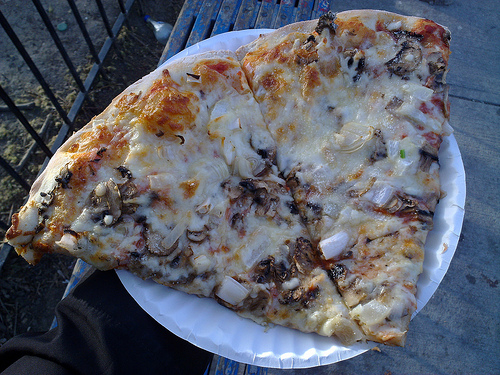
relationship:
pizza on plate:
[4, 9, 450, 350] [116, 28, 467, 371]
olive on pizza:
[397, 44, 425, 74] [4, 9, 450, 350]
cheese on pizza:
[200, 111, 261, 164] [4, 9, 450, 350]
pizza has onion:
[4, 9, 450, 350] [216, 274, 253, 309]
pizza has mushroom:
[4, 9, 450, 350] [109, 180, 125, 225]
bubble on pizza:
[137, 76, 200, 145] [4, 9, 450, 350]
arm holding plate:
[1, 265, 214, 373] [116, 28, 467, 371]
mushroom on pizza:
[109, 180, 125, 225] [4, 9, 450, 350]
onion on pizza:
[216, 274, 253, 309] [4, 9, 450, 350]